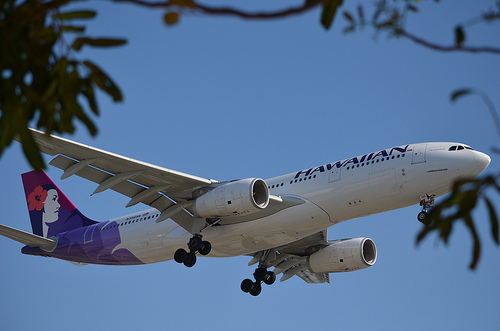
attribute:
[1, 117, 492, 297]
plane — hawaiian airline, flying, large, white, blue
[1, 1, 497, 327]
sky — clear, blue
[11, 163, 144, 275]
graphic — hawaiian, purple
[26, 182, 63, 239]
woman — hawaiian, beautiful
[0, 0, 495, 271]
leaves — on tree, green, in foreground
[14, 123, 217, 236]
right wing — large, white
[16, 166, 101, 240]
tail — colorful, decorated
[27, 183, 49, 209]
flower — red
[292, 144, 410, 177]
writing — "hawaiian"